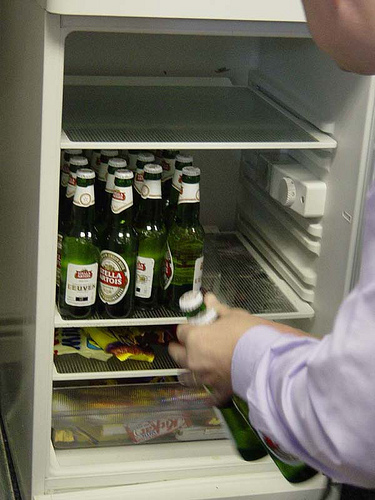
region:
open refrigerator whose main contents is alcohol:
[0, 0, 372, 496]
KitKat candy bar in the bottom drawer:
[120, 409, 189, 439]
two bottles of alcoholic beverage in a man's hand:
[177, 288, 316, 473]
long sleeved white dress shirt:
[228, 182, 370, 482]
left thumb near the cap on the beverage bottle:
[200, 288, 246, 311]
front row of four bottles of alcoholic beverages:
[56, 162, 202, 318]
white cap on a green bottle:
[180, 164, 204, 177]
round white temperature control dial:
[276, 177, 296, 208]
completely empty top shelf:
[62, 74, 339, 147]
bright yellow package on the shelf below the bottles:
[81, 328, 155, 362]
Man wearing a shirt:
[228, 159, 373, 489]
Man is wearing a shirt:
[226, 149, 374, 492]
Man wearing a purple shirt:
[228, 170, 373, 492]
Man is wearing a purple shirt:
[227, 156, 371, 489]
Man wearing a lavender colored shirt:
[223, 152, 371, 489]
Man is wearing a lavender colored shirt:
[230, 153, 372, 494]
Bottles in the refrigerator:
[59, 143, 213, 318]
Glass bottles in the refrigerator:
[58, 145, 211, 318]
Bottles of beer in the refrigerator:
[52, 147, 210, 321]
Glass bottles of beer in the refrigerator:
[57, 143, 208, 318]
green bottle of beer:
[61, 165, 96, 316]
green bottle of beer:
[100, 170, 135, 306]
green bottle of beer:
[138, 160, 160, 299]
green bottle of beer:
[165, 165, 204, 287]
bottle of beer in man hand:
[172, 285, 265, 463]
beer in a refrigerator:
[75, 162, 198, 292]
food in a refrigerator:
[61, 333, 143, 356]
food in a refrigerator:
[126, 420, 213, 440]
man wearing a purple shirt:
[229, 325, 364, 475]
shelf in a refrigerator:
[273, 122, 333, 179]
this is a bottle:
[167, 160, 215, 325]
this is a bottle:
[137, 159, 171, 317]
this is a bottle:
[100, 162, 149, 318]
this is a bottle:
[63, 158, 102, 312]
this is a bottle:
[172, 271, 255, 474]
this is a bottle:
[162, 133, 204, 267]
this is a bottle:
[130, 143, 169, 212]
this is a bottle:
[100, 153, 130, 213]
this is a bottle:
[66, 143, 100, 223]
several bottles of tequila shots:
[64, 180, 208, 309]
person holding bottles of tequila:
[179, 290, 324, 488]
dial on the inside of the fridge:
[274, 177, 299, 210]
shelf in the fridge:
[231, 288, 289, 306]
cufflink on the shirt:
[241, 334, 262, 365]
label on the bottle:
[63, 262, 95, 312]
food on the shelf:
[60, 329, 160, 362]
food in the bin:
[58, 391, 210, 442]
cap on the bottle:
[175, 286, 204, 314]